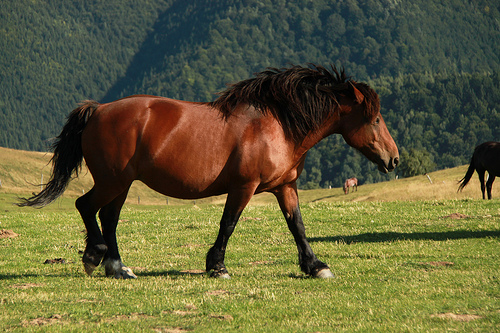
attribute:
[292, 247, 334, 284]
horse foot — black, brown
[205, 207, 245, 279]
legs —  black,  horse's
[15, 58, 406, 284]
horse field —  large,  brown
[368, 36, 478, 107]
tree — short, green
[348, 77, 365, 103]
ear —  brown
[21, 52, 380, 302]
horse —  black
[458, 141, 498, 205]
horse — black, brown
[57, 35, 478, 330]
horse — walking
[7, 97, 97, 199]
tail —  black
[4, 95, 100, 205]
tail —  bushy ,  black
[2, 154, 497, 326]
field — green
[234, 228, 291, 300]
grass — green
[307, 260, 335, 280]
hooves —  large,  gray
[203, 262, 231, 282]
hooves —  large,  gray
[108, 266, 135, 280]
hooves —  large,  gray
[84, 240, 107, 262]
hooves —  large,  gray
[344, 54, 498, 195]
tree — green, short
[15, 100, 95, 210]
hair —  long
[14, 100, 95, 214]
tail —  horse's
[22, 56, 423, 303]
horse — brown, blaack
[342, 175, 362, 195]
horse —  brown and white,  grazing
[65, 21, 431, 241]
horse — running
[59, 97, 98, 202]
tail —  horse's,  with brown top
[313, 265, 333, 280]
hoof —  gray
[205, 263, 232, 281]
hoof —  gray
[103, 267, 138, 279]
hoof —  gray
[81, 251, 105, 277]
hoof —  gray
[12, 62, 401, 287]
horse — brown, walking,  large, black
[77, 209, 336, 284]
legs —  brown and black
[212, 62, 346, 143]
hair —  brown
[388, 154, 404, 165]
nose —  horse's,   brown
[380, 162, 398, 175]
mouth —   closed,  horse's